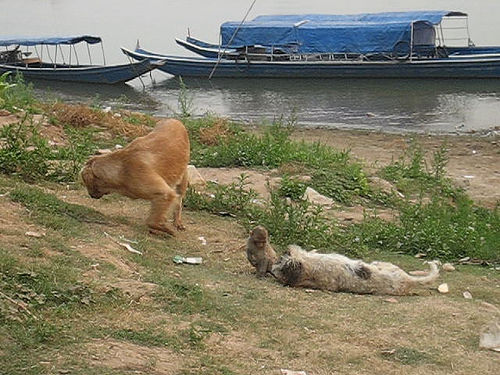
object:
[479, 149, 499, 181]
dirt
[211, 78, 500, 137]
water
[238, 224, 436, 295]
dog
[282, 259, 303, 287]
spots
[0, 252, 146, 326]
ground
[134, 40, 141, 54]
anchor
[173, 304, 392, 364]
ground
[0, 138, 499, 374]
hill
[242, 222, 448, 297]
monkey playing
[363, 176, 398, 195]
rock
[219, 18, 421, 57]
cover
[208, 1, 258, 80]
anchor rope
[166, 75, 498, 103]
boat reflection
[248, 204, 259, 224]
weeds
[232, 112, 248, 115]
ripples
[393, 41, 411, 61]
old tire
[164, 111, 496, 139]
water shoreline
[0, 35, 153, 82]
blue boat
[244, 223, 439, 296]
monkey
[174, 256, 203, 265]
piece of trash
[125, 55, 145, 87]
large paddle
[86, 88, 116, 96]
body of water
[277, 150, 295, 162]
patches of grass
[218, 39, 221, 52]
ropes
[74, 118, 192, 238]
dog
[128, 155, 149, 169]
brown fur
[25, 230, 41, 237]
trash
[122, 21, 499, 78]
boat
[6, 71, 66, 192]
plants growing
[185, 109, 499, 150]
sandy shore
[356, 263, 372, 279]
dog's spot